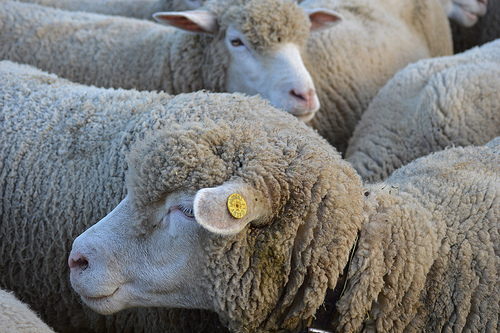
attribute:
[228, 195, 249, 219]
tag — yellow, plastic, small, golden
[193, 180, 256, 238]
ear — white, medium-sized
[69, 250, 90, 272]
nose — pink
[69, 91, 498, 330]
lamb — smiling, white, medium-sized, standing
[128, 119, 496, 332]
fur — tan, cream-colored, curly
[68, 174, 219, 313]
face — white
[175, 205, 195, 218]
eyes — small, black, almond-shaped, closed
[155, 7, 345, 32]
ears — sticking out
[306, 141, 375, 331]
neck — wrinkled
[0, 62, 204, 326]
wool — grey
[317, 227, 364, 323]
collar — black, leather